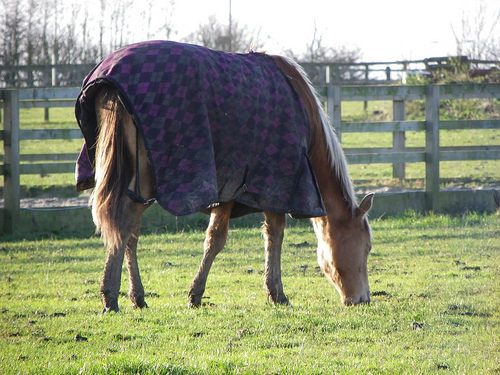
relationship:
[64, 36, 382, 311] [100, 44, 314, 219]
horse covered with blanket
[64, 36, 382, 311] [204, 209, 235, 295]
horse has leg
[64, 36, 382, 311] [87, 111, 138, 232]
horse has tail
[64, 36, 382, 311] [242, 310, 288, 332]
horse eating grass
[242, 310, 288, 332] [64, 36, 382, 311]
grass eaten by horse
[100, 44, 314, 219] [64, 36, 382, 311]
blanket on horse